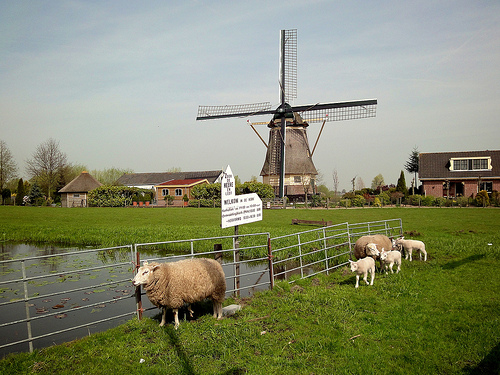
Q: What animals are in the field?
A: Sheep.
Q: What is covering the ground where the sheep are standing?
A: Green grass.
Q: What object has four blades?
A: The windmill.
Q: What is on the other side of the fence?
A: A pond.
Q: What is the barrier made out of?
A: Metal.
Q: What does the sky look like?
A: Light blue and clear.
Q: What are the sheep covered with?
A: Wool.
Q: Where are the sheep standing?
A: In a green field.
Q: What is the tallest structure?
A: A windmill.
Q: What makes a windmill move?
A: The wind.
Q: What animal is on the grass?
A: Sheep.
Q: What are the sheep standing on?
A: Green grass.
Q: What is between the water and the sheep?
A: A metal fence.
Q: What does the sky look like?
A: Cloudy.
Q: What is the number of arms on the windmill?
A: Four.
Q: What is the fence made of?
A: Metal.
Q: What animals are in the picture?
A: Sheep.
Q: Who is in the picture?
A: Only the sheep.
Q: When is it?
A: Day time.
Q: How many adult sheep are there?
A: Two.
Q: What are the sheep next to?
A: A fence.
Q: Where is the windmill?
A: Behind the sheep.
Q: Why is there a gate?
A: To block the sheep from the water.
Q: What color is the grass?
A: Green.